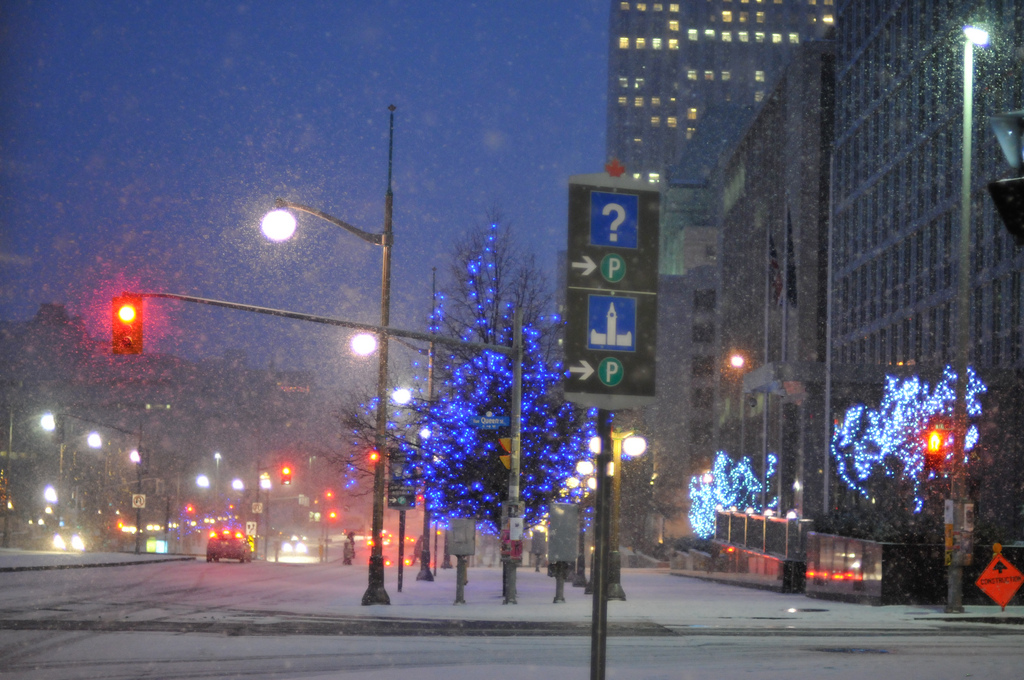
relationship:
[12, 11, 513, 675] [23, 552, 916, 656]
snow falling on street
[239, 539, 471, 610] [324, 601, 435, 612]
sidewalk covered in snow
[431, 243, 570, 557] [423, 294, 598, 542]
tree has lights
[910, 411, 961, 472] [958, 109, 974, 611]
light on pole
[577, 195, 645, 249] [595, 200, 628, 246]
sign with question mark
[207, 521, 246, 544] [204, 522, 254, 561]
lights on car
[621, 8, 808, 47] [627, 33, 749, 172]
windows on building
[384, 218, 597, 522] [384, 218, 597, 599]
christmas lights on tree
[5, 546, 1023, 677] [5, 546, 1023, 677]
snow on road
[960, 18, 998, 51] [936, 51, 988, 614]
lamp on post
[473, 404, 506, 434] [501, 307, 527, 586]
sign on pole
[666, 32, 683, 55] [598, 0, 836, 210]
window on a building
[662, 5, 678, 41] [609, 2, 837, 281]
window on a building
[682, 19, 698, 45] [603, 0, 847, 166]
window on a building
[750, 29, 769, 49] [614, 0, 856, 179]
window on a building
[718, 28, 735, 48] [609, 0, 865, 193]
window on a building